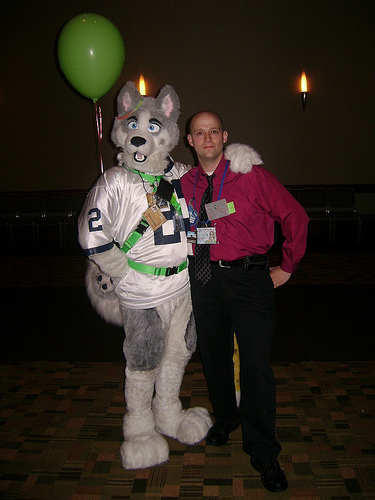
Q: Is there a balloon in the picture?
A: Yes, there is a balloon.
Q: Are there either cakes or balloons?
A: Yes, there is a balloon.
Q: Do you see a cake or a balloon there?
A: Yes, there is a balloon.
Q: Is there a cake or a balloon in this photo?
A: Yes, there is a balloon.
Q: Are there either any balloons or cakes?
A: Yes, there is a balloon.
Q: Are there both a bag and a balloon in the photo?
A: No, there is a balloon but no bags.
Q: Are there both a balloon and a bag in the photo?
A: No, there is a balloon but no bags.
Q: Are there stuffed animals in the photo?
A: No, there are no stuffed animals.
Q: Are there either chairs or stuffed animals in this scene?
A: No, there are no stuffed animals or chairs.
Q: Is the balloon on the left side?
A: Yes, the balloon is on the left of the image.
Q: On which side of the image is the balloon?
A: The balloon is on the left of the image.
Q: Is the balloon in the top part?
A: Yes, the balloon is in the top of the image.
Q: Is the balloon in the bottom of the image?
A: No, the balloon is in the top of the image.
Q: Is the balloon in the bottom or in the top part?
A: The balloon is in the top of the image.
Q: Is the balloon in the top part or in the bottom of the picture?
A: The balloon is in the top of the image.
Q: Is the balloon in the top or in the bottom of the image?
A: The balloon is in the top of the image.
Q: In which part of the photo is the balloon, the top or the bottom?
A: The balloon is in the top of the image.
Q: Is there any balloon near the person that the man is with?
A: Yes, there is a balloon near the person.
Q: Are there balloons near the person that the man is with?
A: Yes, there is a balloon near the person.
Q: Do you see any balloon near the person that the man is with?
A: Yes, there is a balloon near the person.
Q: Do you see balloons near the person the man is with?
A: Yes, there is a balloon near the person.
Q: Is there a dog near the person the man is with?
A: No, there is a balloon near the person.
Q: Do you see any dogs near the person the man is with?
A: No, there is a balloon near the person.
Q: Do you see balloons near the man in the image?
A: Yes, there is a balloon near the man.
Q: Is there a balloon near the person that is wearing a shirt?
A: Yes, there is a balloon near the man.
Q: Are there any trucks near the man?
A: No, there is a balloon near the man.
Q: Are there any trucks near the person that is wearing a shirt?
A: No, there is a balloon near the man.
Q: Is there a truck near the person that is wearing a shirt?
A: No, there is a balloon near the man.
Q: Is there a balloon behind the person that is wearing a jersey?
A: Yes, there is a balloon behind the person.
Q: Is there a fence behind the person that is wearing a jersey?
A: No, there is a balloon behind the person.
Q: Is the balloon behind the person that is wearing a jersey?
A: Yes, the balloon is behind the person.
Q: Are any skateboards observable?
A: No, there are no skateboards.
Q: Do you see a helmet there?
A: No, there are no helmets.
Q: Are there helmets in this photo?
A: No, there are no helmets.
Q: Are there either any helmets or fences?
A: No, there are no helmets or fences.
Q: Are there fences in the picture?
A: No, there are no fences.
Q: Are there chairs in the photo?
A: No, there are no chairs.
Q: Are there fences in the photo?
A: No, there are no fences.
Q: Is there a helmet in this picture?
A: No, there are no helmets.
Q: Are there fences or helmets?
A: No, there are no helmets or fences.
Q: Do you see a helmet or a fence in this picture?
A: No, there are no helmets or fences.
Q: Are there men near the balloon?
A: Yes, there is a man near the balloon.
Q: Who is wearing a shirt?
A: The man is wearing a shirt.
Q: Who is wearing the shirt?
A: The man is wearing a shirt.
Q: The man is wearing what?
A: The man is wearing a shirt.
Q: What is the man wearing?
A: The man is wearing a shirt.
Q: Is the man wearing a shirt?
A: Yes, the man is wearing a shirt.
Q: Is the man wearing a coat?
A: No, the man is wearing a shirt.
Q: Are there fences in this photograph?
A: No, there are no fences.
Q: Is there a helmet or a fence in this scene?
A: No, there are no fences or helmets.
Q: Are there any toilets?
A: No, there are no toilets.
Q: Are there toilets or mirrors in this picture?
A: No, there are no toilets or mirrors.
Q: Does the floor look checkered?
A: Yes, the floor is checkered.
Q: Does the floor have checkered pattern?
A: Yes, the floor is checkered.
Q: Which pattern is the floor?
A: The floor is checkered.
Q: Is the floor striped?
A: No, the floor is checkered.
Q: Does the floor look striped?
A: No, the floor is checkered.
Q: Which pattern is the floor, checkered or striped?
A: The floor is checkered.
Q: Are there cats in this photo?
A: No, there are no cats.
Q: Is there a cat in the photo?
A: No, there are no cats.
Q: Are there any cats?
A: No, there are no cats.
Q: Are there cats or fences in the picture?
A: No, there are no cats or fences.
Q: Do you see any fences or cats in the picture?
A: No, there are no cats or fences.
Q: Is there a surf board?
A: No, there are no surfboards.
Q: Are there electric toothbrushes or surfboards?
A: No, there are no surfboards or electric toothbrushes.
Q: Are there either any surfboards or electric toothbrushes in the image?
A: No, there are no surfboards or electric toothbrushes.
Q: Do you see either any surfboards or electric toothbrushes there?
A: No, there are no surfboards or electric toothbrushes.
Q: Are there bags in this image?
A: No, there are no bags.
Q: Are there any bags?
A: No, there are no bags.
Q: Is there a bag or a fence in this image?
A: No, there are no bags or fences.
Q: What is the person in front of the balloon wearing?
A: The person is wearing a jersey.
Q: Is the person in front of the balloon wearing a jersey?
A: Yes, the person is wearing a jersey.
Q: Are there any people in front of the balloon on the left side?
A: Yes, there is a person in front of the balloon.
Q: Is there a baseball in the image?
A: No, there are no baseballs.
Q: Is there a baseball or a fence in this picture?
A: No, there are no baseballs or fences.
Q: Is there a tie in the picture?
A: Yes, there is a tie.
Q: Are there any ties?
A: Yes, there is a tie.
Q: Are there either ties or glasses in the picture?
A: Yes, there is a tie.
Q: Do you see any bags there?
A: No, there are no bags.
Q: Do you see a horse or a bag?
A: No, there are no bags or horses.